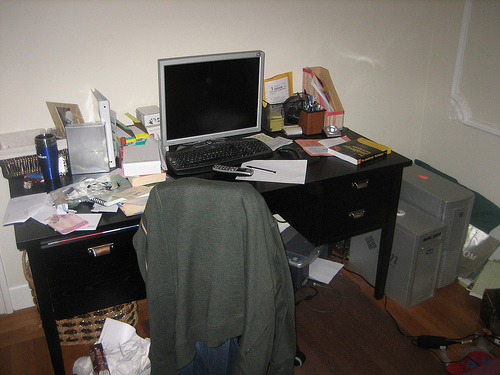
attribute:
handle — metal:
[348, 177, 374, 192]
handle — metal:
[348, 206, 365, 221]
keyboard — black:
[173, 124, 266, 178]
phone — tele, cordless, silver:
[49, 162, 133, 230]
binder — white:
[87, 95, 115, 170]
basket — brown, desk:
[37, 302, 125, 343]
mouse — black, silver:
[273, 128, 312, 173]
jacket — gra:
[195, 197, 244, 262]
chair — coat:
[280, 218, 385, 367]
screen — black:
[172, 70, 251, 134]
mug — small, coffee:
[32, 124, 55, 183]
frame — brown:
[50, 94, 82, 134]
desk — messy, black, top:
[12, 109, 383, 280]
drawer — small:
[328, 141, 407, 249]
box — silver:
[74, 126, 106, 168]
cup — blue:
[34, 149, 69, 191]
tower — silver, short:
[371, 214, 452, 311]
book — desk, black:
[115, 135, 170, 170]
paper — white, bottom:
[252, 153, 291, 181]